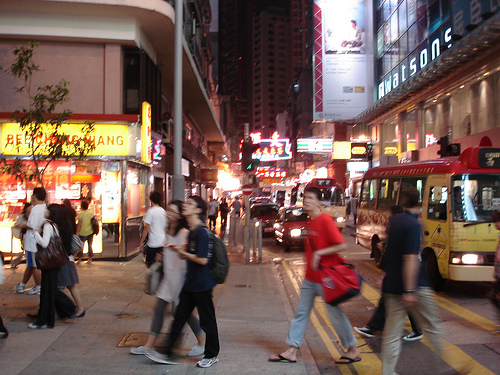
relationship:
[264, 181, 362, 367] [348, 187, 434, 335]
man wearing flip flops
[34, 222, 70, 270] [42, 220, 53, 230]
bag on shoulder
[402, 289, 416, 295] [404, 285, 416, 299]
watch on wrist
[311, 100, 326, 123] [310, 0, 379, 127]
edge of billboard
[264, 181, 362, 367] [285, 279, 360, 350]
man wearing pants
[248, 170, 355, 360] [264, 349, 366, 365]
man wearing black sandals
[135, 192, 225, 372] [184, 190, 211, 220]
man has hair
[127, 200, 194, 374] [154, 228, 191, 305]
woman wearing grey tights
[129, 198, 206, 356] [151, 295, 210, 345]
woman wearing grey tights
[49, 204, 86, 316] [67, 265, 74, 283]
woman wearing skirt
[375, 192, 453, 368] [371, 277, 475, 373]
person wearing tan pants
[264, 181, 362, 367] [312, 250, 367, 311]
man carrying a bag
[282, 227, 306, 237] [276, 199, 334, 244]
headlight of a car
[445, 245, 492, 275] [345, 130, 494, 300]
headlight of a bus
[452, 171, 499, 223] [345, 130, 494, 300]
windshield of a bus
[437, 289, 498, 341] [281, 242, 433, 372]
line in street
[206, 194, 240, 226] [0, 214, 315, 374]
people walking on a sidewalk